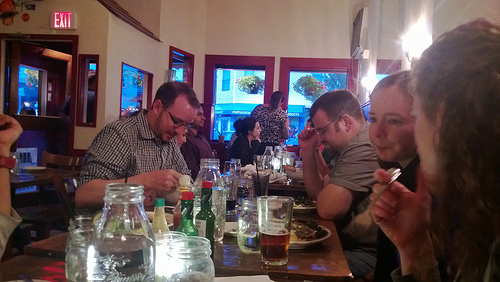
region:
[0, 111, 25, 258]
arm with watch on wrist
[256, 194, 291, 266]
half full glass of beer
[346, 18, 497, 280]
woman holding a fork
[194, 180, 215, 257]
bottle of hot sauce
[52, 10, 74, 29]
lit up exit sign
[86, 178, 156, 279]
ball jar containing water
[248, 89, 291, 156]
woman with pony tail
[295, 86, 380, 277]
man touching his glasses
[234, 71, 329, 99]
two flowering hanging plants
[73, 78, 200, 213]
man with shirt sleeves rolled up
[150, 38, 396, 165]
Three windows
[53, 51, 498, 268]
Six people eating at a table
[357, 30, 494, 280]
Lady holding fork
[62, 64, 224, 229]
Man wearing button down shirt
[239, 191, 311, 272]
Glass with drink in it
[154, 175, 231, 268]
Hot sauce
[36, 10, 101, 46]
exit sign above door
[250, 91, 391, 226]
man wearing a pair of glasses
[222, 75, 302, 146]
women with pony tails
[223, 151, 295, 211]
drink with a straw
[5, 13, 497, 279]
people eating in a restaurant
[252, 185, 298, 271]
half of a glass of beer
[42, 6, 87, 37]
exit sign by the door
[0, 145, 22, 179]
red watch on woman's wrist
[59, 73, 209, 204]
man eating at a restaurant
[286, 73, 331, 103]
hanging planter outside with red flowers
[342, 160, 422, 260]
woman's hand with fork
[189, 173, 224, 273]
green bottle of tabasco sauce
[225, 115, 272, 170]
woman sitting at a restaurant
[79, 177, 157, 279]
glass bottle of water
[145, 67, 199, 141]
the head of a person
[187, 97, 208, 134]
the head of a person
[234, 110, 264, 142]
the head of a person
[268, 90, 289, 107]
the head of a person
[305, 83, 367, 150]
the head of a person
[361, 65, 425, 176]
the head of a person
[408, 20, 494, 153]
the head of a person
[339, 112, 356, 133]
the ear of a person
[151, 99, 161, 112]
the ear of a person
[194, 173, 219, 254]
a bottle on the table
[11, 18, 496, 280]
People in a restaurant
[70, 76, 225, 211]
Man wears squared shirt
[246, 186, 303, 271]
Glass of beer on table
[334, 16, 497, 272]
Woman holds a fork on right hand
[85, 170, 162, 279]
Bottle with water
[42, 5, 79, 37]
Sign EXIT on top of door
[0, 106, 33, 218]
Man wearing red clock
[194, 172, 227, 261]
Green bottle with red lid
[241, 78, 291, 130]
Woman wearing a ponytail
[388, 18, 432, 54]
Light on left side